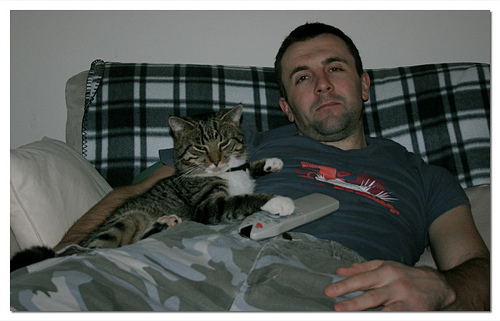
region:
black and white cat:
[133, 137, 257, 224]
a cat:
[124, 101, 264, 319]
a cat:
[87, 72, 218, 289]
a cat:
[178, 141, 288, 309]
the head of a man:
[266, 19, 376, 143]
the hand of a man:
[322, 253, 453, 308]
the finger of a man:
[322, 265, 394, 300]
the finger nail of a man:
[321, 280, 341, 297]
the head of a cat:
[166, 98, 252, 176]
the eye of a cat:
[189, 139, 211, 157]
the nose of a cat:
[206, 153, 225, 168]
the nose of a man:
[309, 63, 337, 95]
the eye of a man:
[289, 68, 316, 91]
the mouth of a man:
[311, 93, 348, 115]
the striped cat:
[34, 103, 292, 239]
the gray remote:
[242, 193, 339, 237]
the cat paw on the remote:
[260, 190, 295, 215]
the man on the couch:
[53, 21, 498, 319]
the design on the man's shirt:
[300, 160, 401, 209]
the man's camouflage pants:
[35, 226, 330, 311]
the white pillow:
[13, 134, 107, 248]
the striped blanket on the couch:
[90, 54, 269, 150]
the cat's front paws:
[256, 148, 294, 215]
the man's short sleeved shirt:
[159, 115, 472, 270]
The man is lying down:
[37, 19, 477, 294]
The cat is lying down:
[53, 93, 277, 269]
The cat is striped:
[58, 114, 272, 267]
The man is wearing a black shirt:
[168, 19, 472, 268]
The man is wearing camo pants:
[53, 233, 438, 313]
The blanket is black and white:
[75, 51, 486, 197]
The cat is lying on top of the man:
[46, 86, 310, 233]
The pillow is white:
[13, 117, 133, 251]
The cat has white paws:
[197, 149, 312, 250]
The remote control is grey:
[225, 173, 371, 240]